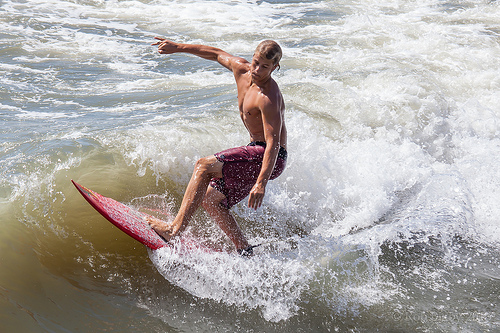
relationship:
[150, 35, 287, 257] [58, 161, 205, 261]
man on sufboard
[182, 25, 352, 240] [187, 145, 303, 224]
man in trunks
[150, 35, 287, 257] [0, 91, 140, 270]
man surfing on waves